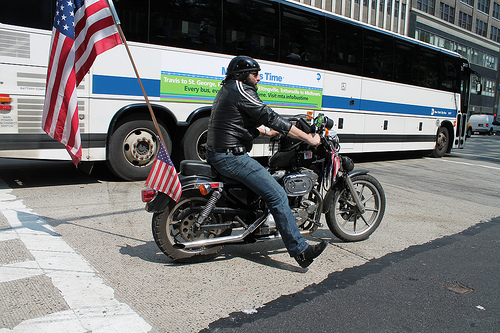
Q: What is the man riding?
A: A motorcycle.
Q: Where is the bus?
A: On the road.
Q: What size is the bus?
A: Large.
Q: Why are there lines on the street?
A: For pedestrians.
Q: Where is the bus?
A: Near the motorcycle.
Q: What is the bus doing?
A: Waiting.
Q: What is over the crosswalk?
A: The back of the bus.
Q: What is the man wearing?
A: Black boots.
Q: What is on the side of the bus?
A: A blue line.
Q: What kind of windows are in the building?
A: Large windows.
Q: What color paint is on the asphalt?
A: White.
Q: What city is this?
A: New York City.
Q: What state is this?
A: New York.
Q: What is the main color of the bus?
A: White.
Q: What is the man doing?
A: Riding on a motorcycle.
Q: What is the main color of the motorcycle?
A: Black.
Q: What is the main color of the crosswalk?
A: White.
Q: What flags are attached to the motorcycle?
A: American flags.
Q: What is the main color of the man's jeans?
A: Blue.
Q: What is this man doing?
A: Straddling a motorcycle.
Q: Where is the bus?
A: On the road.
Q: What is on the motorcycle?
A: Flags.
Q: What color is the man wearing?
A: Black.